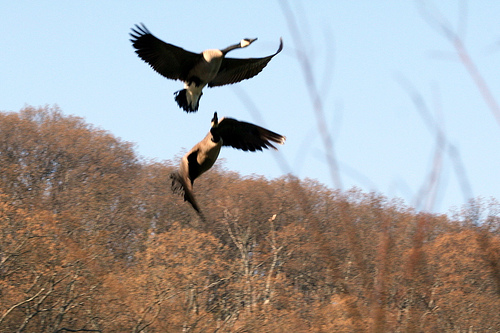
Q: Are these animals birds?
A: Yes, all the animals are birds.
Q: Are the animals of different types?
A: No, all the animals are birds.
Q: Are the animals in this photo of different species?
A: No, all the animals are birds.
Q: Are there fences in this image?
A: No, there are no fences.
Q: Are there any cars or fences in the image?
A: No, there are no fences or cars.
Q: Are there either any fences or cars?
A: No, there are no fences or cars.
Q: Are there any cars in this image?
A: No, there are no cars.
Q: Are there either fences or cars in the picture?
A: No, there are no cars or fences.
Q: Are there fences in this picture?
A: No, there are no fences.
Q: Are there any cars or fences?
A: No, there are no fences or cars.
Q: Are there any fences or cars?
A: No, there are no fences or cars.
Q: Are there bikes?
A: No, there are no bikes.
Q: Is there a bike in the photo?
A: No, there are no bikes.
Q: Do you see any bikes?
A: No, there are no bikes.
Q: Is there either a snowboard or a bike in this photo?
A: No, there are no bikes or snowboards.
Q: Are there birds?
A: Yes, there is a bird.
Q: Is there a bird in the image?
A: Yes, there is a bird.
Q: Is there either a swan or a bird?
A: Yes, there is a bird.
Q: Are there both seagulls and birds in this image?
A: No, there is a bird but no seagulls.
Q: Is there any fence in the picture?
A: No, there are no fences.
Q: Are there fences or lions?
A: No, there are no fences or lions.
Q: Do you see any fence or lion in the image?
A: No, there are no fences or lions.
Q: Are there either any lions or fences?
A: No, there are no fences or lions.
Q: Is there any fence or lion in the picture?
A: No, there are no fences or lions.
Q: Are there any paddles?
A: No, there are no paddles.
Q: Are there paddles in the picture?
A: No, there are no paddles.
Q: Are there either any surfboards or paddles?
A: No, there are no paddles or surfboards.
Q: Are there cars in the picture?
A: No, there are no cars.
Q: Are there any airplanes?
A: No, there are no airplanes.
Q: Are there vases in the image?
A: No, there are no vases.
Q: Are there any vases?
A: No, there are no vases.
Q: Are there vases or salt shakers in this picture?
A: No, there are no vases or salt shakers.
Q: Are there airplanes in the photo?
A: No, there are no airplanes.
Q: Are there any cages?
A: No, there are no cages.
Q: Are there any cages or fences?
A: No, there are no cages or fences.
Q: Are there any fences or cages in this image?
A: No, there are no cages or fences.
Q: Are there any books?
A: No, there are no books.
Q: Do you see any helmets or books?
A: No, there are no books or helmets.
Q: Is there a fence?
A: No, there are no fences.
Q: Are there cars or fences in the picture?
A: No, there are no fences or cars.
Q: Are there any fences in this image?
A: No, there are no fences.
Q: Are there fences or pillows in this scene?
A: No, there are no fences or pillows.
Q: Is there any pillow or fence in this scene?
A: No, there are no fences or pillows.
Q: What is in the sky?
A: The clouds are in the sky.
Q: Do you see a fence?
A: No, there are no fences.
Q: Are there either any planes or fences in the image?
A: No, there are no fences or planes.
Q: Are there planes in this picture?
A: No, there are no planes.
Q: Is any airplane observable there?
A: No, there are no airplanes.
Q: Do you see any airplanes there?
A: No, there are no airplanes.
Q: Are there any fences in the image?
A: No, there are no fences.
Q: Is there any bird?
A: Yes, there is a bird.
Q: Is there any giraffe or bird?
A: Yes, there is a bird.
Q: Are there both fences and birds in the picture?
A: No, there is a bird but no fences.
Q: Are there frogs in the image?
A: No, there are no frogs.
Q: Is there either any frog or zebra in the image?
A: No, there are no frogs or zebras.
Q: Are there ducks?
A: No, there are no ducks.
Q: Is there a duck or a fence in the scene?
A: No, there are no ducks or fences.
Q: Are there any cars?
A: No, there are no cars.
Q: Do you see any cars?
A: No, there are no cars.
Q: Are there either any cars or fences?
A: No, there are no cars or fences.